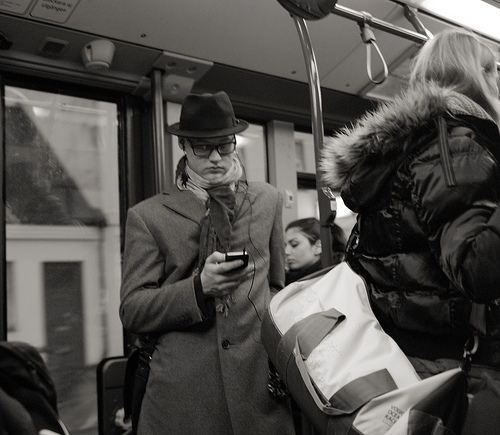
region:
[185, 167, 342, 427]
a woman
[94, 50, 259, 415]
a woman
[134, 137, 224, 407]
a woman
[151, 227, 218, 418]
a woman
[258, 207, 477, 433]
a large white bag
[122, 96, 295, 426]
a man using a cellphone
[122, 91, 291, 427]
a man listing to ear buds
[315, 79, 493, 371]
a winter coat with fur lining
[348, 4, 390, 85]
a public transportation grab strap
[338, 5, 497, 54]
a public transportation grab bar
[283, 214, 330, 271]
a woman's face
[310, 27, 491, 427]
a woman standing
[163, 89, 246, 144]
a man's black hat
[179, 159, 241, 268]
a man's neck scarf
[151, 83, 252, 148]
Man is wearing a dark colored hat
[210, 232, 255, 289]
Man is holding a cell phone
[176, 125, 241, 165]
Man is wearing eyeglasses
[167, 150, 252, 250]
Man is wearing a scarf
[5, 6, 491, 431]
Photo is in black and white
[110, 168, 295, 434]
Man is wearing a coat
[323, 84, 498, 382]
Woman is wearing a black coat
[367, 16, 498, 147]
Woman has light colored hair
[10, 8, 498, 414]
People are inside a subway train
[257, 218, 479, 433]
Woman is carrying a white bag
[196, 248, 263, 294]
black cell phone in hand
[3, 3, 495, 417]
people riding a light rail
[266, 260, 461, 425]
white tote bag someone is holding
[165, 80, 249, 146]
man wearing a black stetson hat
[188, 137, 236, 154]
man wearing black glasses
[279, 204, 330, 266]
woman looking down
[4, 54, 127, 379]
window showing a white house on the outside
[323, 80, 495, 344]
woman wearing a black down jacket with fur hat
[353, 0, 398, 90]
silver ring to hold on above on a rail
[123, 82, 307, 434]
a man in a wool overcoat and scarf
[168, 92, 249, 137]
the hat on the man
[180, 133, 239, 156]
the glasses on the man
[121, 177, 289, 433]
the man's long coat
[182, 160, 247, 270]
the scarf on the man's neck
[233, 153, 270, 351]
the black wire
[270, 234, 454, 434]
the bag in front of the man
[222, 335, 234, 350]
the last button on the man's coat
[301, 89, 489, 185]
the fur on the woman's hood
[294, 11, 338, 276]
the pole on the bus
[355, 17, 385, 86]
the hanging strap on the pole